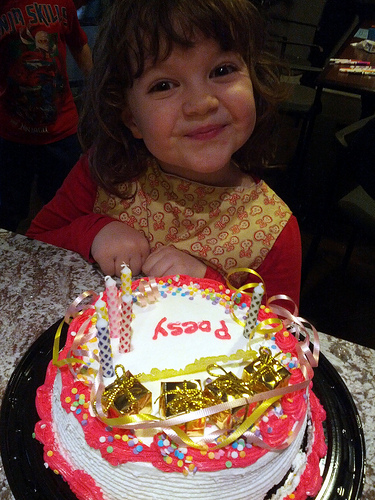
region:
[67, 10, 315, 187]
a young girl smiling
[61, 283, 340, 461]
a small birthday cake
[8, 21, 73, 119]
a boy with red shirt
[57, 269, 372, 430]
white birthday cake on table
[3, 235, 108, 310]
a marble table in background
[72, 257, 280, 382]
cake with some candles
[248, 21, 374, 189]
grey chair in background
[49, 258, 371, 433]
pink frosting on cake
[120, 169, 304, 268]
girl wearing yellow shirt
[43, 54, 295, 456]
girl having birthday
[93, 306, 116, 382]
unlit black and white candle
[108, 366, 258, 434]
small gold boxes on a cake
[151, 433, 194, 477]
rainbow sprinkles and pink frosting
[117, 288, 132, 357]
red and white candle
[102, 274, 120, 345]
pink and white candle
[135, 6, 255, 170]
little girl smiling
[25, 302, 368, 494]
cake on a black platter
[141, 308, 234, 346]
Poesy in red icing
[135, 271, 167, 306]
curly pink ribbon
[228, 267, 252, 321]
curly gold ribbon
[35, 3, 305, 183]
girl with bright eyes smiling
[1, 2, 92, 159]
person in the back wearing graphic t-shirt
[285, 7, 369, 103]
pens on top of a surface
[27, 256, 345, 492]
cake with pink and white icing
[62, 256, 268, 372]
name written between candles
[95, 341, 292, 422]
gold boxes with gold cords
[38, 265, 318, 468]
pastel ribbons around edge of cake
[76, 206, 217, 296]
curled hands touching each other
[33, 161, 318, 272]
yellow jumper with faces above bows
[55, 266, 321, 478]
circular sprinkles around cake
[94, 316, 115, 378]
Blue candle on the birthday cake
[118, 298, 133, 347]
Red candle on birthday cake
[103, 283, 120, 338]
Pink candle on birthday cake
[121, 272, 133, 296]
Yellow candle on cake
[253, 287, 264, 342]
Dark green candle on birthday cake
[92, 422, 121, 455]
Red frosting with sprinkles on cake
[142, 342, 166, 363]
White frosting on birthday cake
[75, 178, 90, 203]
Small part of little girl's red shirt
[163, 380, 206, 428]
Gold presents on birthday cake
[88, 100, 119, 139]
Small patch of brunette hair of little girl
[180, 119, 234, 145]
Little girl's smile.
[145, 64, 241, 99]
Small girl's eyes.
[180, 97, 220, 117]
Small girl's nose.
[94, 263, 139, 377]
Five candles on a cake.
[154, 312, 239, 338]
The word 'Peasy' on a cake.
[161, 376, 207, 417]
Gold decoration box on the cake.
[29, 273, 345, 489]
A pretty decorated birthday cake.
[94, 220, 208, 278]
Little girl's hands that are resting on the table.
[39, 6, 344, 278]
A cute smiling little girl.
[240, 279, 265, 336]
A green birthday candle.